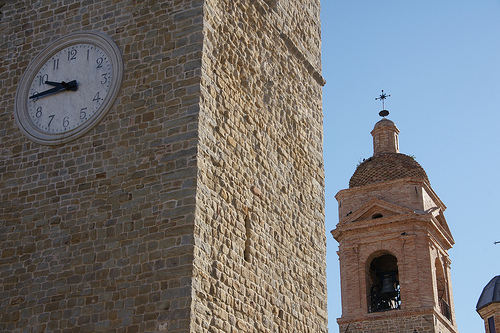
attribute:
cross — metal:
[365, 81, 401, 119]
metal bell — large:
[365, 261, 411, 313]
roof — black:
[474, 280, 495, 305]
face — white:
[29, 46, 104, 122]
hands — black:
[25, 73, 74, 103]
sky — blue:
[333, 8, 497, 178]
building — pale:
[331, 84, 458, 330]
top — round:
[338, 96, 445, 196]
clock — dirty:
[13, 25, 138, 176]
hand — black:
[32, 74, 78, 97]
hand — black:
[26, 84, 79, 103]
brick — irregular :
[241, 186, 251, 196]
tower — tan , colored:
[332, 119, 457, 331]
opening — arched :
[361, 250, 397, 311]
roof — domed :
[350, 153, 424, 182]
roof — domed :
[352, 151, 430, 183]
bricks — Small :
[102, 259, 120, 268]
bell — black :
[373, 268, 398, 297]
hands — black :
[26, 75, 76, 100]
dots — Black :
[86, 46, 89, 49]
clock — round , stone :
[13, 30, 127, 148]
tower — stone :
[0, 0, 329, 330]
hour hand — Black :
[46, 79, 78, 86]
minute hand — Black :
[32, 84, 79, 100]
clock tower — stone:
[2, 1, 329, 328]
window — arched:
[368, 241, 402, 322]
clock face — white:
[13, 37, 131, 147]